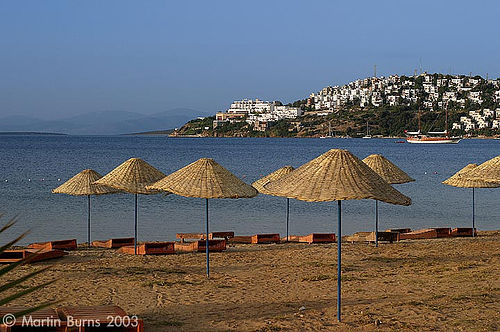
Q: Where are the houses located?
A: On the island's hill.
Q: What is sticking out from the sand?
A: Umbrellas.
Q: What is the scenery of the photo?
A: Beach.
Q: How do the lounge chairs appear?
A: Empty.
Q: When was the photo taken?
A: 2003.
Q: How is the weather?
A: Clear and sunny.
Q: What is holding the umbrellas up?
A: Poles.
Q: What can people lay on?
A: Lounge chairs.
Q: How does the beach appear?
A: Calm and clear.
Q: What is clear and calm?
A: The beach.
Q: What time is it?
A: Afternoon.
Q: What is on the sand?
A: Umbrellas.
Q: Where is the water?
A: Next to the sand.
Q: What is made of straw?
A: Umbrella.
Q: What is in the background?
A: Houses.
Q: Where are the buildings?
A: On a hill.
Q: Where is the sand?
A: On the ground.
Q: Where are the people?
A: None in photo.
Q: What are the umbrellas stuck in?
A: The sand.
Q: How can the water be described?
A: Calm.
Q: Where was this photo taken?
A: On a beach.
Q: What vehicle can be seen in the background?
A: Boat.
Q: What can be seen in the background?
A: Buildings.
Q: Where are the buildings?
A: On a hill.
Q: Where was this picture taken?
A: On the beach.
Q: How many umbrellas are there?
A: 8.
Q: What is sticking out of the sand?
A: Umbrellas.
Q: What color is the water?
A: Blue.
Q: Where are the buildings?
A: On the hill.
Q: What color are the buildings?
A: White.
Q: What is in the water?
A: Boat.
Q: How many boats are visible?
A: 1.